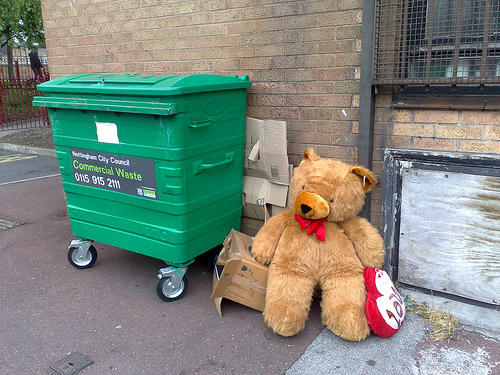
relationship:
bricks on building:
[240, 30, 417, 235] [89, 10, 403, 255]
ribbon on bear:
[293, 213, 327, 242] [257, 166, 387, 343]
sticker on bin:
[64, 144, 175, 188] [61, 65, 231, 272]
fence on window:
[344, 8, 478, 101] [374, 13, 458, 100]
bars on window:
[361, 38, 485, 88] [374, 13, 458, 100]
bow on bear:
[292, 204, 347, 242] [268, 169, 409, 316]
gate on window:
[367, 1, 499, 90] [353, 0, 491, 94]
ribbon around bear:
[288, 211, 335, 245] [249, 147, 385, 343]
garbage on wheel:
[28, 67, 253, 267] [62, 232, 100, 273]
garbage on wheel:
[28, 67, 253, 267] [152, 264, 192, 305]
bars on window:
[375, 3, 484, 81] [369, 1, 483, 103]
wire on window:
[370, 0, 484, 99] [369, 1, 483, 103]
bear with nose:
[249, 147, 387, 347] [287, 190, 331, 226]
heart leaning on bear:
[359, 261, 411, 341] [249, 147, 387, 347]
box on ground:
[204, 224, 282, 324] [2, 139, 483, 373]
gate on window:
[367, 2, 484, 91] [403, 1, 482, 77]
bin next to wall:
[31, 73, 255, 267] [38, 1, 482, 299]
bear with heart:
[249, 147, 387, 347] [363, 267, 407, 338]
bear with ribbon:
[249, 147, 385, 343] [290, 213, 337, 246]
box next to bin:
[210, 227, 269, 317] [31, 73, 255, 267]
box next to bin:
[240, 115, 295, 236] [31, 73, 255, 267]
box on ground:
[210, 227, 269, 317] [2, 139, 483, 373]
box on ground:
[232, 109, 298, 236] [2, 139, 483, 373]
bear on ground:
[249, 147, 385, 343] [2, 139, 483, 373]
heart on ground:
[363, 267, 407, 338] [2, 139, 483, 373]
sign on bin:
[65, 140, 159, 200] [31, 73, 255, 267]